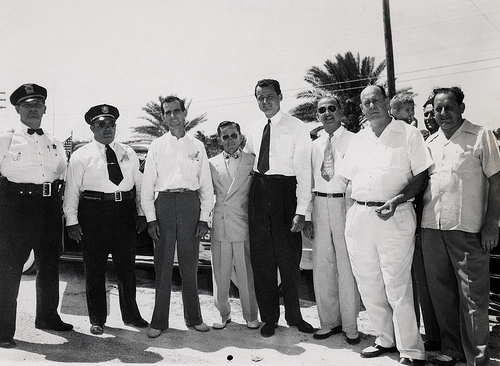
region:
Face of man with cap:
[7, 72, 49, 132]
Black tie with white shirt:
[60, 133, 151, 220]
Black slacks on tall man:
[240, 161, 315, 346]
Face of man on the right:
[426, 80, 489, 128]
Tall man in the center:
[241, 66, 326, 356]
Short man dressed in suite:
[201, 101, 268, 341]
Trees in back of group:
[281, 35, 417, 125]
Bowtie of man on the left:
[16, 120, 56, 138]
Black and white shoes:
[351, 322, 427, 360]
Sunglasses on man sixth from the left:
[313, 101, 345, 116]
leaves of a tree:
[328, 62, 345, 74]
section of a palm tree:
[348, 67, 357, 96]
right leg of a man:
[313, 251, 328, 304]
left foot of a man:
[196, 319, 201, 331]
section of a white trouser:
[389, 240, 396, 266]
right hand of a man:
[148, 224, 156, 237]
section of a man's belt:
[111, 193, 124, 200]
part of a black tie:
[112, 164, 116, 179]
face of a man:
[221, 126, 242, 150]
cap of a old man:
[93, 110, 106, 116]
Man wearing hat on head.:
[7, 74, 68, 132]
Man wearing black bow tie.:
[22, 122, 69, 155]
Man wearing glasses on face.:
[82, 111, 150, 156]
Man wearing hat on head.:
[86, 97, 169, 142]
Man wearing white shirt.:
[152, 127, 228, 228]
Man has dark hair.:
[155, 90, 209, 129]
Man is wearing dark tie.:
[244, 117, 303, 202]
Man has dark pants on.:
[258, 198, 318, 309]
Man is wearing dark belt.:
[314, 174, 361, 215]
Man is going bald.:
[352, 79, 397, 136]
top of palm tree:
[302, 59, 390, 94]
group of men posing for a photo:
[0, 72, 498, 364]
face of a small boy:
[389, 94, 416, 123]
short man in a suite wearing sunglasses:
[202, 116, 264, 346]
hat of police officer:
[82, 102, 126, 128]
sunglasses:
[317, 104, 339, 115]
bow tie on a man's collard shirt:
[25, 125, 47, 140]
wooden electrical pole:
[379, 3, 399, 93]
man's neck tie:
[101, 143, 126, 192]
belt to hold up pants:
[5, 178, 68, 200]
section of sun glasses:
[321, 107, 335, 110]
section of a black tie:
[112, 157, 117, 181]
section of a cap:
[91, 110, 98, 115]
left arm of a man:
[489, 187, 495, 234]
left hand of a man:
[296, 152, 306, 205]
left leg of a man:
[186, 231, 193, 289]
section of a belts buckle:
[41, 185, 51, 193]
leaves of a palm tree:
[324, 82, 344, 87]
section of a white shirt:
[375, 154, 390, 193]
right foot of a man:
[379, 339, 384, 351]